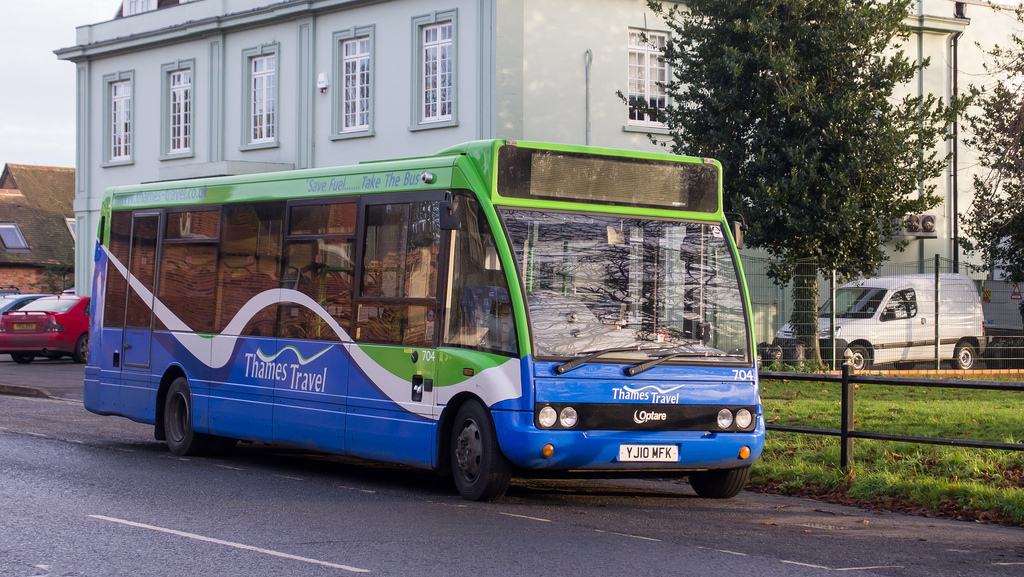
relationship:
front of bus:
[465, 135, 764, 488] [75, 111, 782, 501]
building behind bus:
[51, 3, 1022, 356] [86, 137, 767, 500]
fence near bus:
[758, 364, 1018, 485] [86, 137, 767, 500]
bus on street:
[86, 137, 767, 500] [4, 353, 1022, 572]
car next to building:
[770, 273, 1024, 370] [51, 3, 1022, 356]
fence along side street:
[732, 255, 1022, 372] [751, 344, 1020, 379]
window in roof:
[4, 219, 28, 248] [1, 199, 77, 266]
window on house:
[4, 219, 28, 248] [2, 197, 78, 297]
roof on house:
[1, 199, 77, 266] [2, 197, 78, 297]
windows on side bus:
[107, 189, 518, 358] [86, 137, 767, 500]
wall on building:
[103, 100, 682, 498] [75, 29, 650, 485]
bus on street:
[83, 139, 767, 501] [75, 424, 281, 571]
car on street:
[770, 273, 1024, 370] [43, 420, 242, 570]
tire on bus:
[397, 379, 532, 518] [49, 139, 806, 496]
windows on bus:
[106, 189, 520, 360] [75, 111, 782, 501]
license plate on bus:
[619, 444, 679, 461] [49, 139, 806, 496]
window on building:
[170, 67, 192, 154] [65, 22, 776, 452]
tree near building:
[633, 16, 932, 390] [64, 11, 978, 457]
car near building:
[762, 203, 991, 407] [64, 33, 918, 463]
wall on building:
[72, 0, 652, 185] [65, 22, 776, 452]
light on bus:
[539, 406, 580, 429] [88, 145, 799, 521]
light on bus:
[539, 406, 580, 429] [80, 134, 772, 571]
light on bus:
[539, 406, 580, 429] [49, 139, 806, 496]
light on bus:
[539, 406, 580, 429] [103, 152, 810, 490]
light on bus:
[539, 406, 580, 429] [75, 111, 782, 501]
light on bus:
[539, 406, 580, 429] [60, 152, 789, 479]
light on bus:
[525, 379, 588, 446] [49, 139, 806, 496]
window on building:
[422, 19, 452, 122] [54, 33, 772, 507]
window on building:
[317, 39, 397, 139] [64, 35, 751, 435]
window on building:
[142, 63, 205, 157] [80, 29, 672, 395]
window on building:
[138, 44, 214, 163] [58, 29, 884, 501]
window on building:
[422, 19, 452, 122] [501, 5, 633, 77]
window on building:
[402, 11, 491, 126] [447, 35, 582, 116]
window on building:
[422, 19, 452, 122] [350, 40, 621, 181]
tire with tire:
[451, 399, 512, 501] [133, 363, 213, 444]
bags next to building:
[762, 321, 812, 373] [55, 6, 976, 166]